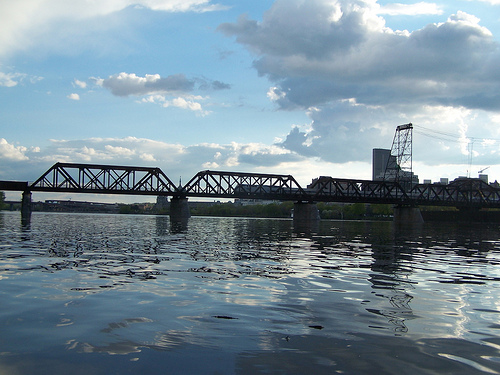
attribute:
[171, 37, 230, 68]
sky — blue, clouds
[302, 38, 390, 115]
cloud — white, drifting, puff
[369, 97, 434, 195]
building — tall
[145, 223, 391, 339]
water — glassy, blue, murky, calm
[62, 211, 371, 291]
shoreline — far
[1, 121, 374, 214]
bridge — black, cross, support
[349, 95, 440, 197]
city — skyline, cluster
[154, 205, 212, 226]
base — concrete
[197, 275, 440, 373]
river — bank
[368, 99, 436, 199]
tower — shaped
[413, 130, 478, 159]
power — line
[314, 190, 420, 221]
tree — row